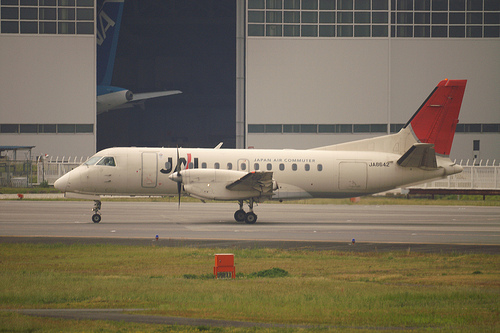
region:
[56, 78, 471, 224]
White plane on the runway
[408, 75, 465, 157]
Orange colored tail of plane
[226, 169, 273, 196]
Left wing of plane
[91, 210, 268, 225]
Three wheels of plane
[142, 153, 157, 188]
A door on the side of plane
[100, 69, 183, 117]
A plane in the hanger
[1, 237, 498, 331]
Green grass beside runway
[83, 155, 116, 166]
Windows on the cockpit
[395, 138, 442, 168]
Short back wing of plane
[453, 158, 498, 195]
White fence made of metal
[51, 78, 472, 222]
airplane on the runway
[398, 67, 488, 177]
tail of the plane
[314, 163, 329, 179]
window on the plane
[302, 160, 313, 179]
window on the plane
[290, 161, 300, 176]
window on the plane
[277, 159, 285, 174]
window on the plane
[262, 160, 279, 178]
window on the plane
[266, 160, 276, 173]
window on the plane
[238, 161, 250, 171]
window on the plane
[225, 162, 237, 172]
window on the plane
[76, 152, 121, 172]
the cockpit of a plane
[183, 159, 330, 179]
the passenger windows on a plane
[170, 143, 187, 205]
the prop on a plane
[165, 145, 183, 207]
the propeller on a plane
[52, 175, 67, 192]
the nosecone on a plane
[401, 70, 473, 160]
the tail-fin of a plane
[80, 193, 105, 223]
the nose-gear on a plane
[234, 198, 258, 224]
the landing gear on a plane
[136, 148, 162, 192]
the loading door on a plane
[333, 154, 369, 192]
the cargo door on a plane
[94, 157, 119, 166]
a window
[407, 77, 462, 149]
tail of the airplane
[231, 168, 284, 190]
the wing on the airplane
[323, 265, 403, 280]
dirt in the grass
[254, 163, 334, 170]
windows on the plane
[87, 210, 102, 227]
front wheel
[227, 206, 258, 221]
back wheel on the airplane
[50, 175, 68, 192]
nose of the airplane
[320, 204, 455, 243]
the roadway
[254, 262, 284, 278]
a patch of green grass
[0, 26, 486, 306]
A plane has landed at the airport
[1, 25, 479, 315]
The plane is delivering its passengers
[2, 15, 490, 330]
The plane is carrying airline customers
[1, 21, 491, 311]
The airliner is for short distances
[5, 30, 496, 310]
The plane is taking people home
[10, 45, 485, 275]
The plan is ready to take off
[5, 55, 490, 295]
The plane is cleared for takeoff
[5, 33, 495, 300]
The plane is doing preflight checks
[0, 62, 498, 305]
The passenger plane is only half full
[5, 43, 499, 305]
The plane has already been fueled